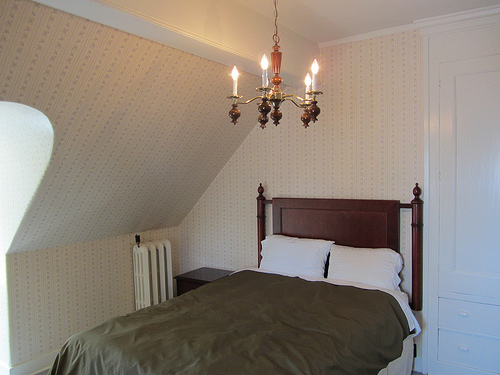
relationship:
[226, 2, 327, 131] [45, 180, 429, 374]
chandelier over bed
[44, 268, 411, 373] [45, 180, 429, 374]
blanket on bed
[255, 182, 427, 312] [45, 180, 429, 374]
headboard on bed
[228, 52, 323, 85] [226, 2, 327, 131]
lightbulbs in chandelier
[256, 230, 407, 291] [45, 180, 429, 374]
pillows on bed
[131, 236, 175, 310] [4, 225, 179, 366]
radiator against wall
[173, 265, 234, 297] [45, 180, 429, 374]
nightstand next to bed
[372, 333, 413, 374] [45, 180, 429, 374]
bedskirt of bed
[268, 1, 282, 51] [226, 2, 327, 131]
chain of chandelier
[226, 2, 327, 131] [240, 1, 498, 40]
chandelier on ceiling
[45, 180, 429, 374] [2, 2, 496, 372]
bed in room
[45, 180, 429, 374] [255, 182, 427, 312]
bed has headboard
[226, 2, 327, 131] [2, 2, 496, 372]
light in room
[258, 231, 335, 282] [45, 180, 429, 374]
pillow on bed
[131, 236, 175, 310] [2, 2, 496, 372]
heater in room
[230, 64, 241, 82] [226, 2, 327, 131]
lightbulb on fixture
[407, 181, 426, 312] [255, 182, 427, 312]
post on headboard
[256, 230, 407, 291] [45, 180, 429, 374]
pillows in cot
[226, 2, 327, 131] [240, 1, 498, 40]
light on ceiling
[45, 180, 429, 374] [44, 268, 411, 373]
bed with sheets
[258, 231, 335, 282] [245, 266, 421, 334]
pillow with sheet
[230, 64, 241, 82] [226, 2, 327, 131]
lightbulb for chandelier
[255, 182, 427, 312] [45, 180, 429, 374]
headboard for bed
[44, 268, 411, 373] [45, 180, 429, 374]
comforter for bed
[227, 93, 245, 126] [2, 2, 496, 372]
holder in photo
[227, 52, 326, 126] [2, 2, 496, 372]
lighting in photo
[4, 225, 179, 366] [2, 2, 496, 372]
wall in photo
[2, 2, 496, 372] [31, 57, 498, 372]
bedroom of home